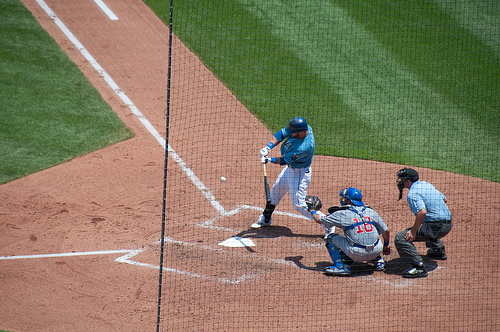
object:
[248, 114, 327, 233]
batter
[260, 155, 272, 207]
bat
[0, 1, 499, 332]
field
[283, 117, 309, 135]
blue helmet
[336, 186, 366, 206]
blue helmet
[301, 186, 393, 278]
catcher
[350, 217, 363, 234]
red numbers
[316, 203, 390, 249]
gray shirt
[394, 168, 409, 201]
black face mask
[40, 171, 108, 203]
air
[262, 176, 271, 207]
black and tan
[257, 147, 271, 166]
white and blue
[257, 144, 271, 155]
gloves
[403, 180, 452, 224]
blue shirt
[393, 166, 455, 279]
umpire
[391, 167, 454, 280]
baseball umpire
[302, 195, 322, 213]
black leather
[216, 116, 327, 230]
flight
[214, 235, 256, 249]
white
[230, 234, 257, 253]
plate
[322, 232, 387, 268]
pair of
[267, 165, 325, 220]
pair of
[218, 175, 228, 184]
baseball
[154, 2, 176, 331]
baseline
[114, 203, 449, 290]
home plate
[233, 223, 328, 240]
shadow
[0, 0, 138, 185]
green grass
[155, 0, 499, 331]
net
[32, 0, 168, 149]
lines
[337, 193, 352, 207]
mask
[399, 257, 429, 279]
black shoes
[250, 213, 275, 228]
white shoes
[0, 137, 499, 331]
base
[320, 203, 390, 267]
uniform